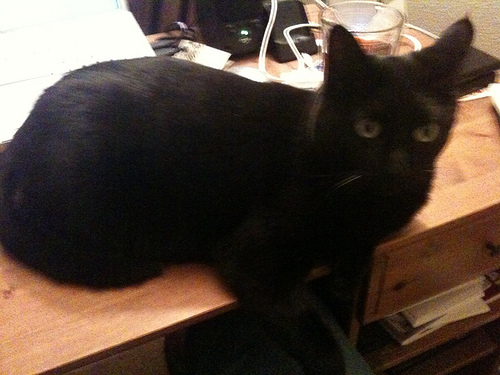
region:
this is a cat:
[3, 18, 483, 347]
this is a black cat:
[9, 10, 477, 347]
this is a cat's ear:
[327, 16, 360, 83]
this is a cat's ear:
[425, 10, 470, 90]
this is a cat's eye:
[350, 111, 380, 139]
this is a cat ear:
[411, 114, 442, 141]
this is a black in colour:
[28, 120, 86, 235]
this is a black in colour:
[148, 70, 253, 190]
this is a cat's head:
[312, 21, 463, 214]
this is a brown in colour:
[11, 286, 111, 347]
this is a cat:
[100, 41, 350, 284]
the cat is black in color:
[196, 132, 286, 233]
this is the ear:
[320, 16, 359, 71]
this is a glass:
[355, 4, 417, 41]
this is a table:
[25, 295, 142, 360]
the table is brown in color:
[35, 282, 130, 362]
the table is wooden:
[72, 300, 134, 353]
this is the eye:
[349, 103, 384, 142]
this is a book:
[408, 285, 483, 323]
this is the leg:
[266, 281, 363, 372]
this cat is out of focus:
[5, 8, 480, 373]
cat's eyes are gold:
[347, 109, 447, 149]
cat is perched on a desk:
[0, 3, 498, 363]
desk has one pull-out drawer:
[356, 203, 498, 325]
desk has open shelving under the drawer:
[361, 277, 498, 373]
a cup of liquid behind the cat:
[312, 0, 409, 76]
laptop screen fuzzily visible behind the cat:
[0, 2, 167, 151]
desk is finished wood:
[2, 250, 234, 372]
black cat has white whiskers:
[306, 168, 375, 193]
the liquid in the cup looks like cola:
[315, 0, 405, 75]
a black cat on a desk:
[4, 5, 495, 373]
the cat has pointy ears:
[308, 5, 482, 89]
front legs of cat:
[222, 246, 409, 373]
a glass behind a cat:
[304, 5, 416, 97]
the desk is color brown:
[12, 1, 497, 372]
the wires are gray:
[245, 1, 422, 92]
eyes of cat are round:
[351, 108, 443, 149]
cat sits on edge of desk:
[12, 8, 497, 373]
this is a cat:
[7, 11, 478, 336]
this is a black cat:
[6, 15, 488, 366]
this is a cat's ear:
[319, 19, 363, 87]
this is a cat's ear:
[419, 15, 476, 78]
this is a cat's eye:
[353, 108, 383, 143]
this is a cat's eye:
[413, 120, 439, 145]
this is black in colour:
[18, 149, 106, 242]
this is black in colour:
[141, 119, 268, 217]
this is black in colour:
[296, 162, 380, 231]